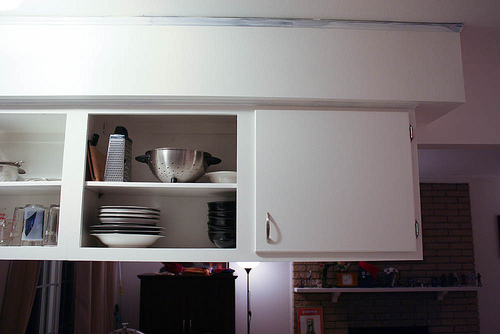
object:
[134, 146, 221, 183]
strainer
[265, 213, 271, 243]
handle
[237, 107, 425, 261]
cabinet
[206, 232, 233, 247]
bowls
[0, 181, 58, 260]
cabinet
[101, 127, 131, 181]
grater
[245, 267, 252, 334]
stand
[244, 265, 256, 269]
lamp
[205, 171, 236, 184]
bowl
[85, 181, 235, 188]
shelf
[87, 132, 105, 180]
items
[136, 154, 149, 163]
handle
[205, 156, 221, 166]
handle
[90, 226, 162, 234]
plates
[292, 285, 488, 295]
shelf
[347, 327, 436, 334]
fireplace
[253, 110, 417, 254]
door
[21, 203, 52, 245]
glass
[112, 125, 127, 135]
handle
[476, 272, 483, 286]
figure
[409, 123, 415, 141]
hinge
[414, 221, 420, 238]
hinge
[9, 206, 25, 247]
mug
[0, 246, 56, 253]
shelf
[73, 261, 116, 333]
curtain panel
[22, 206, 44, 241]
design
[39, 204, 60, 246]
glasses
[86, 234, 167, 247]
dishes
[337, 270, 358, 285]
clock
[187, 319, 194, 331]
handle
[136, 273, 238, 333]
cabinet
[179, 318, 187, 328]
handle